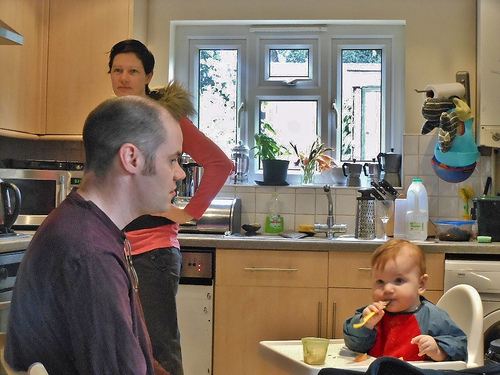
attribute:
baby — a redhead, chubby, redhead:
[341, 234, 467, 363]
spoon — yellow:
[347, 297, 394, 331]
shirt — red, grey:
[343, 299, 471, 361]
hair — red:
[369, 235, 427, 277]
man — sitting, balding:
[5, 96, 190, 374]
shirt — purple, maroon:
[6, 183, 155, 373]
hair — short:
[80, 99, 167, 179]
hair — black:
[102, 37, 157, 73]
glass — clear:
[376, 199, 392, 243]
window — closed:
[169, 19, 401, 186]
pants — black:
[132, 248, 186, 372]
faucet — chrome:
[311, 183, 346, 242]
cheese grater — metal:
[352, 187, 377, 243]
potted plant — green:
[252, 122, 290, 187]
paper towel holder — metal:
[410, 70, 472, 110]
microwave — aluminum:
[5, 167, 87, 230]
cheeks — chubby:
[372, 285, 414, 306]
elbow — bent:
[200, 149, 236, 182]